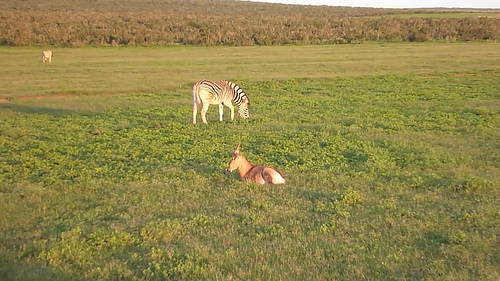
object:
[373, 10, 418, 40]
leaves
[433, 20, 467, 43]
trees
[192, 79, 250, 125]
animal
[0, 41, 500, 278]
grass field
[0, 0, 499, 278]
field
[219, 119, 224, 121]
feet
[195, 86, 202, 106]
tail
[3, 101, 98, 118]
shadow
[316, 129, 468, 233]
grass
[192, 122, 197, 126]
feet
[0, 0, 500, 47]
distance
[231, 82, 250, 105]
mane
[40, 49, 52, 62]
animal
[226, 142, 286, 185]
animal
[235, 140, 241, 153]
horns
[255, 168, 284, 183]
haunch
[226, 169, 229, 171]
nose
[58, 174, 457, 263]
grass